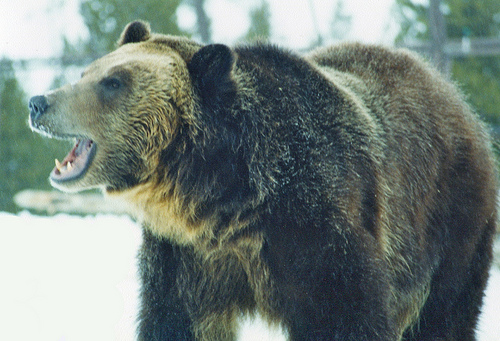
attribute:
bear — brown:
[256, 128, 434, 325]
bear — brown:
[335, 133, 460, 213]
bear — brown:
[227, 49, 357, 204]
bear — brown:
[229, 111, 395, 211]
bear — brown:
[278, 60, 407, 242]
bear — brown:
[327, 43, 396, 209]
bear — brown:
[302, 65, 435, 258]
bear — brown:
[238, 33, 352, 201]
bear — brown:
[245, 62, 378, 251]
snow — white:
[64, 205, 113, 319]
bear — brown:
[237, 0, 409, 184]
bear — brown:
[97, 80, 434, 290]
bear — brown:
[196, 131, 397, 222]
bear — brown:
[259, 106, 413, 262]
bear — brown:
[185, 60, 373, 289]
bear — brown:
[246, 66, 376, 216]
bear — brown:
[140, 66, 349, 206]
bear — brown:
[245, 57, 321, 202]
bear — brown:
[231, 41, 405, 277]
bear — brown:
[148, 10, 390, 240]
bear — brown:
[191, 50, 351, 235]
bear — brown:
[154, 73, 384, 280]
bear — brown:
[23, 18, 494, 340]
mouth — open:
[29, 119, 94, 190]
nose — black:
[28, 91, 47, 116]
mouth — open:
[21, 117, 104, 187]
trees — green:
[55, 2, 215, 201]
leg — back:
[407, 269, 487, 339]